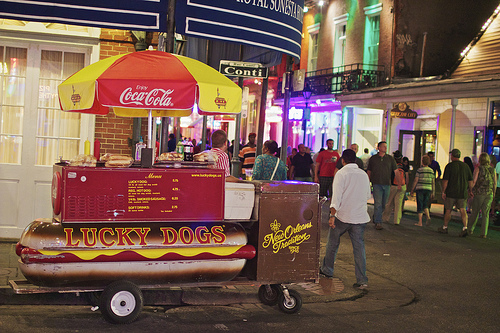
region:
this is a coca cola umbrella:
[52, 53, 244, 124]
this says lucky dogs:
[60, 221, 229, 251]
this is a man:
[315, 147, 373, 294]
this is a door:
[0, 34, 102, 239]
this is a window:
[0, 40, 90, 170]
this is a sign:
[215, 58, 269, 79]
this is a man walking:
[361, 138, 398, 233]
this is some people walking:
[390, 138, 497, 240]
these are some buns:
[102, 151, 130, 171]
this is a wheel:
[100, 281, 145, 327]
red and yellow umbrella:
[54, 48, 258, 109]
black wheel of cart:
[104, 286, 139, 321]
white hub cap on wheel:
[117, 293, 135, 303]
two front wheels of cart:
[248, 285, 303, 309]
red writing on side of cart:
[57, 219, 229, 247]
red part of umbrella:
[91, 48, 186, 112]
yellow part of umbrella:
[192, 66, 236, 108]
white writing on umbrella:
[108, 81, 192, 115]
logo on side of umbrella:
[105, 78, 186, 118]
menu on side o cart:
[110, 168, 182, 218]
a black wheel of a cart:
[102, 285, 145, 323]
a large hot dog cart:
[12, 149, 326, 319]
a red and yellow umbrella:
[59, 45, 240, 132]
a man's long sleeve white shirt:
[325, 163, 376, 224]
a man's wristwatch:
[326, 211, 338, 219]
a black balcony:
[302, 61, 378, 100]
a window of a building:
[355, 13, 381, 72]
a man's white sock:
[461, 224, 470, 230]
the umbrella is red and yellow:
[52, 50, 124, 220]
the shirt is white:
[321, 167, 376, 228]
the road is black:
[404, 265, 461, 320]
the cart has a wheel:
[97, 270, 155, 322]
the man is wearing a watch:
[325, 209, 337, 224]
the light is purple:
[295, 106, 337, 137]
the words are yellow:
[265, 207, 316, 260]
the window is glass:
[2, 47, 25, 170]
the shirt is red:
[315, 147, 337, 180]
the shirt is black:
[435, 156, 476, 204]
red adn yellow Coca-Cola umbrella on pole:
[56, 42, 241, 146]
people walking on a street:
[170, 130, 499, 289]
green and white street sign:
[217, 57, 269, 78]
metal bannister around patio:
[271, 62, 384, 104]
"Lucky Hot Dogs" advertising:
[13, 222, 255, 288]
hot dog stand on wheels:
[11, 46, 320, 325]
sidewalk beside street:
[0, 244, 354, 303]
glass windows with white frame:
[0, 30, 98, 239]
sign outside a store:
[385, 102, 415, 119]